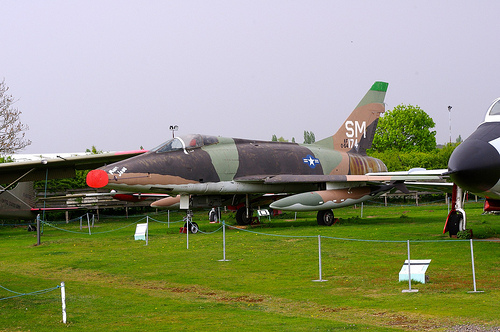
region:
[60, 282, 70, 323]
a small white pole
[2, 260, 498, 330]
a strip of dead grass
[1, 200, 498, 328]
the field is covered in glass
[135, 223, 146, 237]
a white and blue sign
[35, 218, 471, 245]
the line is green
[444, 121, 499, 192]
the nose is black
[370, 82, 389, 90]
tip of tail is green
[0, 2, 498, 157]
the sky is smoggy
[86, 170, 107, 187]
the nose is red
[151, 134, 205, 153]
canopy of the jet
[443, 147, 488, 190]
black color nose of the aircraft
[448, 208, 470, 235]
wheel of the plane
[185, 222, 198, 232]
front wheel of the plane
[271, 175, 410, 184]
wing of the aircraft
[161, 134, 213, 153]
cockpit of the aircraft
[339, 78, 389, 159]
tail wing and rudder of aircraft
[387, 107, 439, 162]
green tree visible at background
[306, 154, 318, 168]
blue circle with white star on body of aircraft.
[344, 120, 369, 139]
SM mentioned on tail wing of the aircraft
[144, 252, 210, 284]
green color grass grown on ground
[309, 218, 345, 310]
This is a shot pole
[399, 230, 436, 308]
This is a shot pole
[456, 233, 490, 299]
This is a shot pole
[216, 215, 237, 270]
This is a shot pole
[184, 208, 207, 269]
This is a shot pole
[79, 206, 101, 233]
This is a shot pole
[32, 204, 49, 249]
This is a shot pole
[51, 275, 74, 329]
This is a shot pole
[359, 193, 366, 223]
This is a shot pole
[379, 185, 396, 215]
This is a shot pole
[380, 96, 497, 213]
this is a person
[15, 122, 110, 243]
this is a person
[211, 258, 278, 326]
a patch of grass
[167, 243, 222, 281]
a patch of grass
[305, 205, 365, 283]
a patch of grass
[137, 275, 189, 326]
a patch of grass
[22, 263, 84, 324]
a patch of grass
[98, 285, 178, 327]
a patch of grass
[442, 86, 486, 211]
A big plane on the ground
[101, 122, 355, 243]
A big plane on the ground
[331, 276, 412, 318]
A green grass field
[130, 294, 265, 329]
A green grass field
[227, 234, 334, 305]
A green grass field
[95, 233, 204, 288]
A green grass field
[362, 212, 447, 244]
A green grass field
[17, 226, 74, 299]
A green grass field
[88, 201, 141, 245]
A green grass field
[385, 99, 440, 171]
A green tall tree